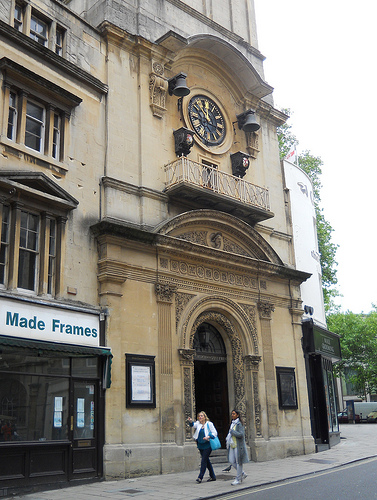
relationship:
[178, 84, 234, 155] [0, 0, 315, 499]
clock on front of building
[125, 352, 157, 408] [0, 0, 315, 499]
frame on front of building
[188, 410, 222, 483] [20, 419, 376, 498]
woman walking on sidewalk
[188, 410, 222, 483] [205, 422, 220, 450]
woman carrying purse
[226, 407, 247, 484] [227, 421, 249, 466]
woman wearing clothes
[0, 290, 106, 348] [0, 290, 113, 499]
advertisement above store front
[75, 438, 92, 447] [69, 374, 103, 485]
mail slot on door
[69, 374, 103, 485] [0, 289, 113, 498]
door on store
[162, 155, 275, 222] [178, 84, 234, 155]
balcony beneath clock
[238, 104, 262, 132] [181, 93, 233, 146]
bell on side of clock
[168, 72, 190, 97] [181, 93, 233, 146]
bell on side of clock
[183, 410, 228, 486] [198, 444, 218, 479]
woman walking in jeans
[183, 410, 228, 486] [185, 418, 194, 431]
woman holding flowers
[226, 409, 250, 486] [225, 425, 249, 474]
woman wearing clothes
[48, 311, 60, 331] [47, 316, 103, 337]
f in frames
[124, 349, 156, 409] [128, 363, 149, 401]
frame with paper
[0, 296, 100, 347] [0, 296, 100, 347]
advertisement that reads advertisement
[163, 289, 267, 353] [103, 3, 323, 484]
archway on a building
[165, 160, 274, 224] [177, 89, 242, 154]
balcony under a clock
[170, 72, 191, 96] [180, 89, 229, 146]
bell to left of a clock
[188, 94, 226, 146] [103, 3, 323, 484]
clock on building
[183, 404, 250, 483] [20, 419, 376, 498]
people on sidewalk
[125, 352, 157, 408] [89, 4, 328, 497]
frame on building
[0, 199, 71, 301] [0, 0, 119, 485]
windows on building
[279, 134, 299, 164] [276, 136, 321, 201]
flag on roof